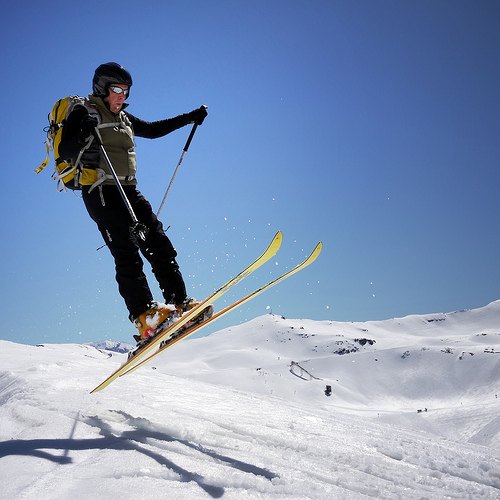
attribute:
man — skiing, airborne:
[46, 61, 213, 334]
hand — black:
[189, 106, 208, 126]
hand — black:
[79, 116, 100, 135]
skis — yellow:
[92, 239, 328, 399]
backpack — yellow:
[42, 97, 102, 187]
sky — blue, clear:
[2, 3, 497, 330]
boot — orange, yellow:
[133, 305, 180, 335]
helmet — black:
[91, 60, 130, 96]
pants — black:
[88, 184, 189, 309]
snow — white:
[7, 308, 498, 499]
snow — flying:
[189, 221, 386, 321]